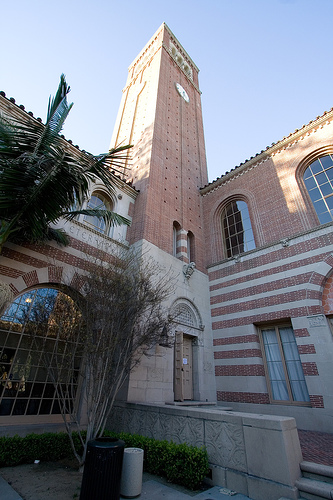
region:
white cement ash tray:
[122, 445, 148, 497]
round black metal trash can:
[80, 435, 128, 499]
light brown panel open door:
[171, 326, 196, 402]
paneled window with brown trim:
[257, 317, 314, 405]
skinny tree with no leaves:
[24, 247, 190, 468]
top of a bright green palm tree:
[1, 72, 133, 252]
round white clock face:
[173, 78, 190, 102]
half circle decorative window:
[163, 297, 209, 331]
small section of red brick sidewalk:
[303, 431, 332, 457]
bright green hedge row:
[147, 433, 208, 496]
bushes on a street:
[166, 425, 221, 490]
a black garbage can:
[82, 435, 143, 498]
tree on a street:
[25, 239, 167, 465]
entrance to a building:
[168, 317, 208, 405]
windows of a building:
[208, 184, 264, 262]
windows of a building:
[78, 180, 131, 238]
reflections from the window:
[2, 266, 94, 421]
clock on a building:
[173, 78, 190, 102]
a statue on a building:
[181, 255, 198, 276]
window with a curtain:
[247, 310, 320, 405]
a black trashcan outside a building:
[79, 430, 124, 498]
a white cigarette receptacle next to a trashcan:
[120, 442, 144, 499]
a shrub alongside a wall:
[96, 428, 213, 485]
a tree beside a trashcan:
[22, 238, 184, 499]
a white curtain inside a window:
[260, 326, 309, 404]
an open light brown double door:
[171, 329, 200, 405]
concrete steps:
[296, 457, 332, 498]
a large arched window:
[1, 277, 98, 418]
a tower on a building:
[90, 20, 208, 243]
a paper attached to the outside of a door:
[180, 354, 190, 367]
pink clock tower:
[141, 14, 202, 211]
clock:
[160, 70, 190, 116]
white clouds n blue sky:
[12, 11, 64, 50]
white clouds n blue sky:
[77, 37, 123, 92]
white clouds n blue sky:
[267, 26, 318, 81]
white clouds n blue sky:
[222, 52, 279, 99]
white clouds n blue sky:
[80, 71, 114, 117]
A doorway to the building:
[170, 329, 203, 404]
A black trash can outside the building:
[81, 435, 121, 499]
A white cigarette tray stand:
[121, 445, 146, 498]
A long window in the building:
[247, 321, 315, 409]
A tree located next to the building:
[35, 253, 178, 466]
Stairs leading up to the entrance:
[293, 455, 332, 496]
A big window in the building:
[1, 264, 106, 433]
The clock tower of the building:
[99, 20, 211, 183]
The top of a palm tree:
[2, 73, 127, 261]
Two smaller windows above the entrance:
[159, 221, 201, 260]